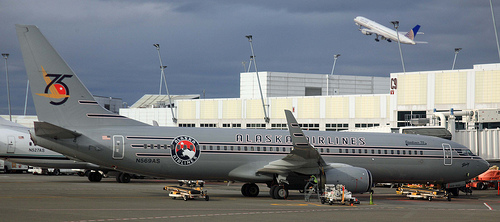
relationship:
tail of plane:
[9, 14, 134, 186] [12, 20, 484, 202]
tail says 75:
[9, 14, 134, 186] [41, 72, 73, 107]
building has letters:
[242, 75, 404, 123] [230, 132, 362, 147]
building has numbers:
[242, 75, 404, 123] [384, 67, 399, 96]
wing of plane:
[253, 105, 339, 192] [12, 20, 484, 202]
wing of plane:
[26, 108, 81, 140] [12, 20, 484, 202]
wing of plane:
[398, 21, 426, 40] [349, 10, 429, 49]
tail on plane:
[9, 14, 134, 186] [12, 20, 484, 202]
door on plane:
[105, 126, 130, 166] [12, 20, 484, 202]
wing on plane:
[253, 105, 339, 192] [12, 20, 484, 202]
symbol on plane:
[169, 127, 196, 167] [12, 20, 484, 202]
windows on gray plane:
[136, 140, 171, 151] [30, 58, 470, 189]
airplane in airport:
[32, 63, 469, 186] [137, 40, 496, 157]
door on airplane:
[105, 126, 130, 166] [32, 63, 469, 186]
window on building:
[245, 122, 267, 129] [170, 57, 498, 157]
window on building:
[245, 122, 267, 129] [168, 59, 493, 136]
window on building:
[245, 122, 267, 129] [171, 65, 498, 137]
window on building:
[245, 122, 267, 129] [173, 92, 397, 129]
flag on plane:
[99, 132, 113, 142] [12, 20, 484, 202]